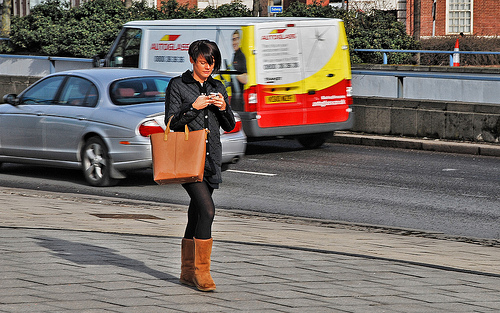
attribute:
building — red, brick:
[402, 0, 499, 42]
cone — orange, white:
[451, 36, 460, 67]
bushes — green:
[316, 1, 418, 66]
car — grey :
[6, 58, 232, 183]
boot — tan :
[194, 237, 214, 290]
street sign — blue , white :
[266, 4, 286, 17]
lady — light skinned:
[146, 45, 249, 301]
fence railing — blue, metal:
[443, 35, 483, 60]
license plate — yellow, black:
[260, 82, 298, 104]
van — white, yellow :
[94, 10, 361, 145]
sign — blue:
[268, 3, 283, 13]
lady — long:
[135, 26, 264, 311]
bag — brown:
[150, 115, 206, 180]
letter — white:
[271, 6, 273, 11]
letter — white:
[274, 7, 277, 8]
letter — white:
[275, 8, 276, 9]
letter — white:
[277, 7, 278, 10]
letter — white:
[279, 7, 280, 9]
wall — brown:
[411, 2, 488, 32]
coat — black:
[171, 78, 193, 105]